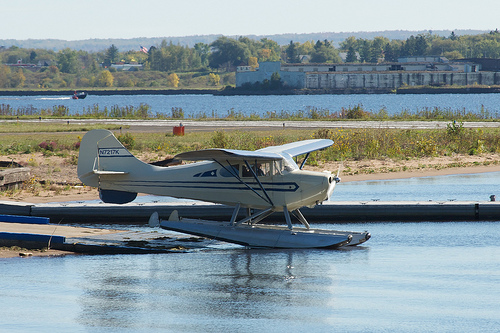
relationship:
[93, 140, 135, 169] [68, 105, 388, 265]
words on side of plane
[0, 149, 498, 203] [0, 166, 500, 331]
dirt on side of water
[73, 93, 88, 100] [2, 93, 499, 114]
boat racing in water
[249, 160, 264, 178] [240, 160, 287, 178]
man in cockpit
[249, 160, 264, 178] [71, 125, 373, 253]
man in plane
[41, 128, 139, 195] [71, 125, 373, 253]
tail of a plane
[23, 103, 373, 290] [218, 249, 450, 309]
plane over water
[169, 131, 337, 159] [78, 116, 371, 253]
wings of airplane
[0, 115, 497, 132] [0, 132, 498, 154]
path of grass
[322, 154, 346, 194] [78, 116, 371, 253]
propellor of airplane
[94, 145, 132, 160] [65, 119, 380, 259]
black lettering on air plane